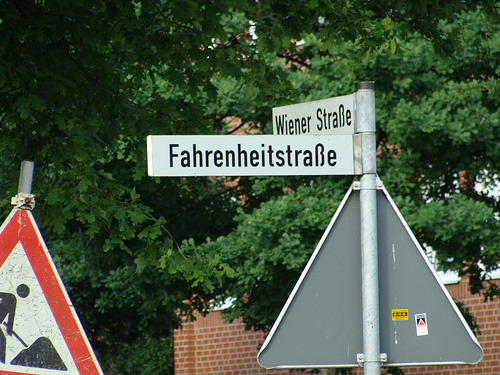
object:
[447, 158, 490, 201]
branch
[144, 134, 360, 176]
sign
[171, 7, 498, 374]
wall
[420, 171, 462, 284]
window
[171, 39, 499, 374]
house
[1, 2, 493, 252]
leaves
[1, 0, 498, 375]
tree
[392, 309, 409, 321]
sticker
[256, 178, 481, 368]
signs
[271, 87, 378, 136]
sign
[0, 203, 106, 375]
red flags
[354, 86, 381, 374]
pole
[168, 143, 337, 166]
marks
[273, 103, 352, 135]
name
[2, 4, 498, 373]
neighborhood